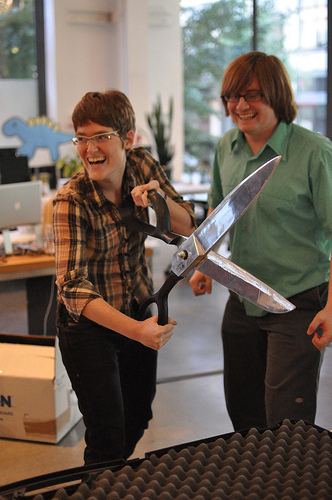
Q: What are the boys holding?
A: Giant scissors.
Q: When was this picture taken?
A: Daytime.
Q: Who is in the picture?
A: Boys.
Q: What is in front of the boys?
A: Eggshell packing.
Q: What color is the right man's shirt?
A: Green.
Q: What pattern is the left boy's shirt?
A: Plaid.